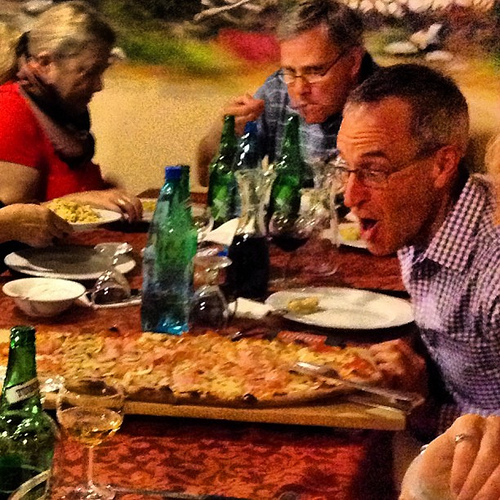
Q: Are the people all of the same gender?
A: No, they are both male and female.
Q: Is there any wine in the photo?
A: Yes, there is wine.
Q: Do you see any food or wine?
A: Yes, there is wine.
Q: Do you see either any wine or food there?
A: Yes, there is wine.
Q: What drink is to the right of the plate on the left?
A: The drink is wine.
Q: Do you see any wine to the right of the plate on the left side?
A: Yes, there is wine to the right of the plate.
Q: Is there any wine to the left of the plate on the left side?
A: No, the wine is to the right of the plate.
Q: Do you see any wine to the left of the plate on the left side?
A: No, the wine is to the right of the plate.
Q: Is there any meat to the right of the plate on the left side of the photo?
A: No, there is wine to the right of the plate.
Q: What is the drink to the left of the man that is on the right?
A: The drink is wine.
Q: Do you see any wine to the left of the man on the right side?
A: Yes, there is wine to the left of the man.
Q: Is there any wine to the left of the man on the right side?
A: Yes, there is wine to the left of the man.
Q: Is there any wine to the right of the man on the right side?
A: No, the wine is to the left of the man.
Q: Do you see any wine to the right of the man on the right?
A: No, the wine is to the left of the man.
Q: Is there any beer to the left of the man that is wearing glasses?
A: No, there is wine to the left of the man.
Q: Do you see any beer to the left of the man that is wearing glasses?
A: No, there is wine to the left of the man.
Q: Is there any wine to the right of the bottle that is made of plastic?
A: Yes, there is wine to the right of the bottle.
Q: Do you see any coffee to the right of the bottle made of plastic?
A: No, there is wine to the right of the bottle.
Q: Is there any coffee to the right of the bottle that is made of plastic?
A: No, there is wine to the right of the bottle.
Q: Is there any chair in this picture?
A: No, there are no chairs.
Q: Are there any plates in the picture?
A: Yes, there is a plate.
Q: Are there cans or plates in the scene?
A: Yes, there is a plate.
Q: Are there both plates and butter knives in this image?
A: No, there is a plate but no butter knives.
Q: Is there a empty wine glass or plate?
A: Yes, there is an empty plate.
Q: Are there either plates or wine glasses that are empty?
A: Yes, the plate is empty.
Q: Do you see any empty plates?
A: Yes, there is an empty plate.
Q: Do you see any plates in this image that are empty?
A: Yes, there is a plate that is empty.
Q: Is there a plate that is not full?
A: Yes, there is a empty plate.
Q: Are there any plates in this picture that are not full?
A: Yes, there is a empty plate.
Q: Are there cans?
A: No, there are no cans.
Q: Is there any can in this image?
A: No, there are no cans.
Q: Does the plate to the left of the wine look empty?
A: Yes, the plate is empty.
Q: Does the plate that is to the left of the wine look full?
A: No, the plate is empty.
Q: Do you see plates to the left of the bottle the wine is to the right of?
A: Yes, there is a plate to the left of the bottle.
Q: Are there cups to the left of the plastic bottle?
A: No, there is a plate to the left of the bottle.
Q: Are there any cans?
A: No, there are no cans.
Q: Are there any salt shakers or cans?
A: No, there are no cans or salt shakers.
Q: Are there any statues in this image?
A: No, there are no statues.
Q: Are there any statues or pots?
A: No, there are no statues or pots.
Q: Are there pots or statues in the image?
A: No, there are no statues or pots.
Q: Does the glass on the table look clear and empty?
A: No, the glass is clear but full.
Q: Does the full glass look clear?
A: Yes, the glass is clear.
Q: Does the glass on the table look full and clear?
A: Yes, the glass is full and clear.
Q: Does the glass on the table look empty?
A: No, the glass is full.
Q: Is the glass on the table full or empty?
A: The glass is full.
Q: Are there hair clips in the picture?
A: No, there are no hair clips.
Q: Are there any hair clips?
A: No, there are no hair clips.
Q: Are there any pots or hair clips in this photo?
A: No, there are no hair clips or pots.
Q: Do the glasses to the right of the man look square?
A: Yes, the glasses are square.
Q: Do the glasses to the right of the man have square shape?
A: Yes, the glasses are square.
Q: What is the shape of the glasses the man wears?
A: The glasses are square.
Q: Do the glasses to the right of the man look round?
A: No, the glasses are square.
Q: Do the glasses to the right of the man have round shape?
A: No, the glasses are square.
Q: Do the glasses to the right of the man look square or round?
A: The glasses are square.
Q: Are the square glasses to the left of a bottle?
A: No, the glasses are to the right of a bottle.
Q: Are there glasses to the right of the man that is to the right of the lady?
A: Yes, there are glasses to the right of the man.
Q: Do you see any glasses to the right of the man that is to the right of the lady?
A: Yes, there are glasses to the right of the man.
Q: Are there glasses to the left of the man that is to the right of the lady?
A: No, the glasses are to the right of the man.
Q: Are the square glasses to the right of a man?
A: Yes, the glasses are to the right of a man.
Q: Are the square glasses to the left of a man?
A: No, the glasses are to the right of a man.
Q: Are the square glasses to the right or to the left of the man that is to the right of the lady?
A: The glasses are to the right of the man.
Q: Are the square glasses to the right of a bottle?
A: Yes, the glasses are to the right of a bottle.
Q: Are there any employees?
A: No, there are no employees.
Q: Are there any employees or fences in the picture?
A: No, there are no employees or fences.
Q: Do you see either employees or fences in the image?
A: No, there are no employees or fences.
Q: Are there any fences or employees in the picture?
A: No, there are no employees or fences.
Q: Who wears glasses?
A: The man wears glasses.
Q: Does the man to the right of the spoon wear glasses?
A: Yes, the man wears glasses.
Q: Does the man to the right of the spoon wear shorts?
A: No, the man wears glasses.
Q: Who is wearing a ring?
A: The man is wearing a ring.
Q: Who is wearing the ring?
A: The man is wearing a ring.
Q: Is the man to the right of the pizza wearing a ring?
A: Yes, the man is wearing a ring.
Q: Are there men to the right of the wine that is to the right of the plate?
A: Yes, there is a man to the right of the wine.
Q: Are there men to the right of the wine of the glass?
A: Yes, there is a man to the right of the wine.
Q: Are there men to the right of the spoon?
A: Yes, there is a man to the right of the spoon.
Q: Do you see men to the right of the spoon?
A: Yes, there is a man to the right of the spoon.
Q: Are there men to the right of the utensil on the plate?
A: Yes, there is a man to the right of the spoon.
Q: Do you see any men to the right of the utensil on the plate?
A: Yes, there is a man to the right of the spoon.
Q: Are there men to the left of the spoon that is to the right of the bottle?
A: No, the man is to the right of the spoon.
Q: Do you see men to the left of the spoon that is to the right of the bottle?
A: No, the man is to the right of the spoon.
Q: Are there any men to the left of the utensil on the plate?
A: No, the man is to the right of the spoon.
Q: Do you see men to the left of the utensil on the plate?
A: No, the man is to the right of the spoon.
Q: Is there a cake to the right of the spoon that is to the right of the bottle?
A: No, there is a man to the right of the spoon.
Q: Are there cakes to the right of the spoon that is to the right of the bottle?
A: No, there is a man to the right of the spoon.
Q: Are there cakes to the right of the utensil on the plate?
A: No, there is a man to the right of the spoon.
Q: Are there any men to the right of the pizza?
A: Yes, there is a man to the right of the pizza.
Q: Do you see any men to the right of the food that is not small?
A: Yes, there is a man to the right of the pizza.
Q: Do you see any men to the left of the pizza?
A: No, the man is to the right of the pizza.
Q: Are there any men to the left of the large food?
A: No, the man is to the right of the pizza.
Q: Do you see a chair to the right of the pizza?
A: No, there is a man to the right of the pizza.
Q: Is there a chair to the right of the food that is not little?
A: No, there is a man to the right of the pizza.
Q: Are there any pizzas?
A: Yes, there is a pizza.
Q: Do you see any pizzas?
A: Yes, there is a pizza.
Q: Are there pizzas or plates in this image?
A: Yes, there is a pizza.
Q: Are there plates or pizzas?
A: Yes, there is a pizza.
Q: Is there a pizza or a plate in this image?
A: Yes, there is a pizza.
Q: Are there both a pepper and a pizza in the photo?
A: No, there is a pizza but no peppers.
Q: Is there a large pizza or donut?
A: Yes, there is a large pizza.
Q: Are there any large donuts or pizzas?
A: Yes, there is a large pizza.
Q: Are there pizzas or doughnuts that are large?
A: Yes, the pizza is large.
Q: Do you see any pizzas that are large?
A: Yes, there is a large pizza.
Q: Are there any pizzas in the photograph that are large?
A: Yes, there is a pizza that is large.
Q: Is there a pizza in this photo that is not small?
A: Yes, there is a large pizza.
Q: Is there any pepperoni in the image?
A: No, there is no pepperoni.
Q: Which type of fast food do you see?
A: The fast food is a pizza.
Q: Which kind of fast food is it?
A: The food is a pizza.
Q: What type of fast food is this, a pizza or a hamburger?
A: That is a pizza.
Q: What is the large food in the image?
A: The food is a pizza.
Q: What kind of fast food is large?
A: The fast food is a pizza.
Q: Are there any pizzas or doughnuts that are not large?
A: No, there is a pizza but it is large.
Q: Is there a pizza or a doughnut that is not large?
A: No, there is a pizza but it is large.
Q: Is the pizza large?
A: Yes, the pizza is large.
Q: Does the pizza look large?
A: Yes, the pizza is large.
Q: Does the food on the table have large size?
A: Yes, the pizza is large.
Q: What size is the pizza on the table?
A: The pizza is large.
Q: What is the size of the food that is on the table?
A: The pizza is large.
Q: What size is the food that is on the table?
A: The pizza is large.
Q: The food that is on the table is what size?
A: The pizza is large.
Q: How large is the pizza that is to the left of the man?
A: The pizza is large.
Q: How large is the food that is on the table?
A: The pizza is large.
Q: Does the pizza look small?
A: No, the pizza is large.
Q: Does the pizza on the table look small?
A: No, the pizza is large.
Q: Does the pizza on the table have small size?
A: No, the pizza is large.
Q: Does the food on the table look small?
A: No, the pizza is large.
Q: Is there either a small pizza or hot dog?
A: No, there is a pizza but it is large.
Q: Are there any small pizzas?
A: No, there is a pizza but it is large.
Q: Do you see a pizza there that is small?
A: No, there is a pizza but it is large.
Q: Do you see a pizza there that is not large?
A: No, there is a pizza but it is large.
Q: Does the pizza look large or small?
A: The pizza is large.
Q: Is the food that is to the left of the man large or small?
A: The pizza is large.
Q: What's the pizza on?
A: The pizza is on the table.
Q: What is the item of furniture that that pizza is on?
A: The piece of furniture is a table.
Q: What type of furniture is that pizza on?
A: The pizza is on the table.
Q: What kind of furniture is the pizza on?
A: The pizza is on the table.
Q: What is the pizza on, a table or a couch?
A: The pizza is on a table.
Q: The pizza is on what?
A: The pizza is on the table.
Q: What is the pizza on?
A: The pizza is on the table.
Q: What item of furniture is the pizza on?
A: The pizza is on the table.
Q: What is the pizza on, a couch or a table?
A: The pizza is on a table.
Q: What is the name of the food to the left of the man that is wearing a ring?
A: The food is a pizza.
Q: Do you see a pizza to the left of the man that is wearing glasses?
A: Yes, there is a pizza to the left of the man.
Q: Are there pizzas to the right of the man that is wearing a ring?
A: No, the pizza is to the left of the man.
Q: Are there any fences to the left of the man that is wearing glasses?
A: No, there is a pizza to the left of the man.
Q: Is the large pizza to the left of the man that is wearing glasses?
A: Yes, the pizza is to the left of the man.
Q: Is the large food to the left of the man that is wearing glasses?
A: Yes, the pizza is to the left of the man.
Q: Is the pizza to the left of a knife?
A: No, the pizza is to the left of the man.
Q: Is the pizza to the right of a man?
A: No, the pizza is to the left of a man.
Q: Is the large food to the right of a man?
A: No, the pizza is to the left of a man.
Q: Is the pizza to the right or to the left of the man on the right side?
A: The pizza is to the left of the man.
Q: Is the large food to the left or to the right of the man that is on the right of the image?
A: The pizza is to the left of the man.